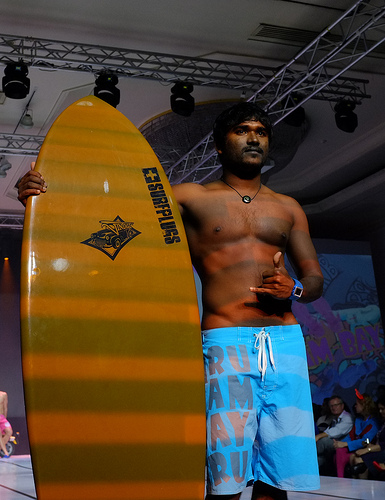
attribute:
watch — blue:
[289, 279, 302, 300]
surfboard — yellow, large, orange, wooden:
[21, 94, 205, 499]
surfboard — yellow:
[1, 82, 206, 355]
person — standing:
[15, 109, 327, 490]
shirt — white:
[325, 410, 351, 433]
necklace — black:
[216, 172, 263, 203]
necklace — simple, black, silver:
[228, 184, 266, 208]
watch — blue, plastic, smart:
[283, 276, 313, 307]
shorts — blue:
[184, 316, 325, 492]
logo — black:
[68, 211, 146, 271]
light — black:
[326, 93, 369, 138]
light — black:
[276, 89, 309, 132]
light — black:
[158, 64, 206, 126]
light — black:
[83, 65, 132, 125]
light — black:
[0, 53, 44, 99]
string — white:
[248, 327, 280, 388]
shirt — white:
[322, 411, 354, 440]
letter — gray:
[224, 338, 254, 377]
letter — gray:
[204, 340, 227, 379]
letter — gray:
[221, 373, 260, 416]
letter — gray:
[200, 374, 231, 414]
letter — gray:
[217, 407, 256, 451]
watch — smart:
[283, 274, 310, 304]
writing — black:
[133, 155, 187, 268]